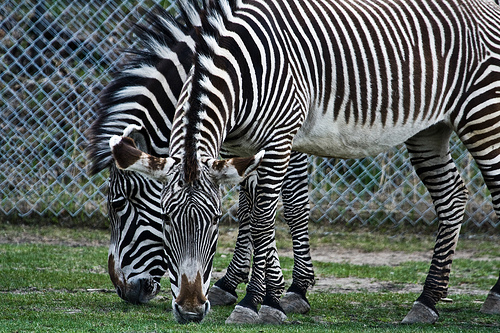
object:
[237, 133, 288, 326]
leg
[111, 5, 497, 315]
zebra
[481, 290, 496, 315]
hoof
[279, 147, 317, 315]
legs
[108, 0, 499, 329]
zebra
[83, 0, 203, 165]
mane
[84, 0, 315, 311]
zebra